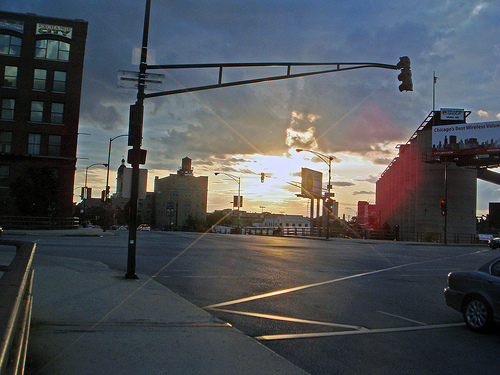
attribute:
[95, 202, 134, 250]
cars — parked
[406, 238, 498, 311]
car — sedan, driving, dark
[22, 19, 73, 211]
buildng — tall, peach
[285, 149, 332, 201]
billboard — white, large, above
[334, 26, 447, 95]
light — attached, overlooking, distant, green, red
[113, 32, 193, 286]
pole — black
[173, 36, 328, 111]
arm — metal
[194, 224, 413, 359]
street — gray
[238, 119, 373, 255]
sun — shining, setting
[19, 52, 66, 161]
windows — dark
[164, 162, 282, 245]
building — old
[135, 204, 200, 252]
car — distant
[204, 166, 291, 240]
sign — advertising, back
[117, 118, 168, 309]
support — metal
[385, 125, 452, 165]
rail — silver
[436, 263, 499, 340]
vehicle — gray, white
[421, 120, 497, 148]
print — red